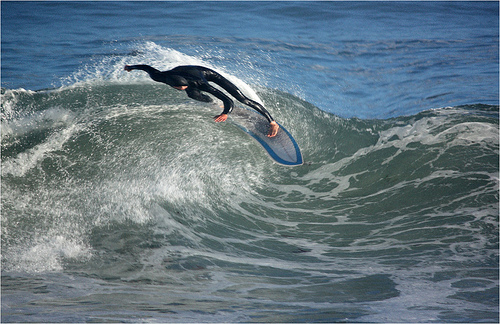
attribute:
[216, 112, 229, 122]
hand — bare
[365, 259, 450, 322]
foam — white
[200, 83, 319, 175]
surfboard — white and blue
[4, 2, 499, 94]
water — blue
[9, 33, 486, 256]
wave — small, foamy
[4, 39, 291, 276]
wave — flat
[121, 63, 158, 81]
arm — extended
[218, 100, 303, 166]
surfboard — white, blue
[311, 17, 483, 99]
water — blue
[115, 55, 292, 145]
man — surfing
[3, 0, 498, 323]
ocean — large, blue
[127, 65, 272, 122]
wetsuit — black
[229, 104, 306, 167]
surfboard — white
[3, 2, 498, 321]
water — blue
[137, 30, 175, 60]
spray — white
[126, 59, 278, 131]
wetsuit — black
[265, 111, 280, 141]
foot — bare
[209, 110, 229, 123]
foot — bare